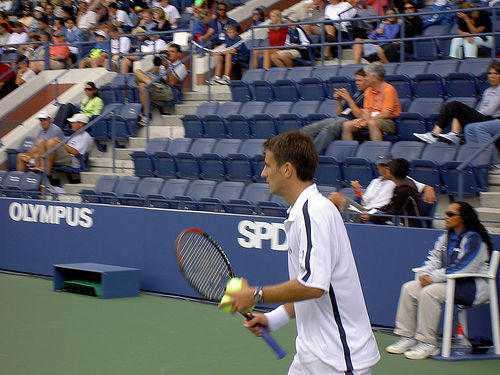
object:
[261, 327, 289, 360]
handle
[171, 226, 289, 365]
racket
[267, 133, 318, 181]
hair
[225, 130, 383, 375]
guy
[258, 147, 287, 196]
face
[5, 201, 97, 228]
writing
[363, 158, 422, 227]
people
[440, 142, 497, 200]
seats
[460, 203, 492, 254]
hair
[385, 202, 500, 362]
person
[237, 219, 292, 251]
letters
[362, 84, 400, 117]
shirt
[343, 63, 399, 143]
people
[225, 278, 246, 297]
balls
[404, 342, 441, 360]
sneakers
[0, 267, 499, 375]
court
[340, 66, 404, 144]
spectator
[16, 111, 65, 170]
men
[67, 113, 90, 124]
hats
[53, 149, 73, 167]
shorts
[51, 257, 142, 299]
stand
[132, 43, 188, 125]
man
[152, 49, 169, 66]
camera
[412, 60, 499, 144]
person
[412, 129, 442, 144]
feet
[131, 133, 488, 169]
row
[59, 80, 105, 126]
person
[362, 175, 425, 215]
shirt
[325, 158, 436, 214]
man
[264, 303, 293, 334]
band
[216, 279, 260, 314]
hand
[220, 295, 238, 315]
balls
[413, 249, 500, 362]
chair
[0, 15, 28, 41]
people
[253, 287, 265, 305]
watch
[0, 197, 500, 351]
wall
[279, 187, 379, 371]
shirt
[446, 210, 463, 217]
sunglasses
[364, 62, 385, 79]
hair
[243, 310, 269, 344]
hand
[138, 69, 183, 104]
chair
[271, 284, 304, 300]
skin